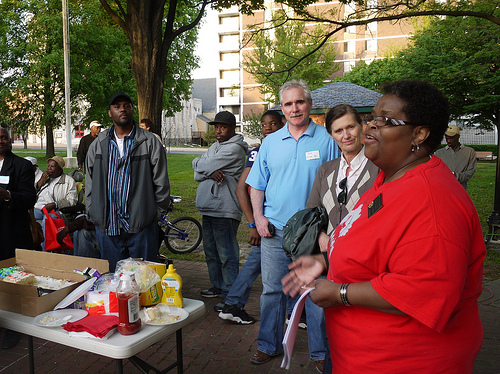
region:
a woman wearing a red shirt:
[278, 79, 488, 371]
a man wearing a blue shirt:
[248, 78, 339, 372]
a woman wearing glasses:
[282, 76, 485, 372]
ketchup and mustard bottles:
[117, 264, 183, 336]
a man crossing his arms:
[192, 108, 248, 300]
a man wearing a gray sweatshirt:
[192, 111, 249, 304]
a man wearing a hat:
[192, 108, 252, 303]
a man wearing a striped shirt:
[80, 90, 172, 266]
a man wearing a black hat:
[82, 88, 172, 260]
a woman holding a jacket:
[283, 104, 380, 372]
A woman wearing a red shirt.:
[361, 65, 451, 365]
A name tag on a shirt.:
[298, 148, 323, 162]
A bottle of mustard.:
[155, 262, 188, 307]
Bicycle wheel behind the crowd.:
[163, 214, 204, 254]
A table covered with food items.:
[1, 251, 197, 363]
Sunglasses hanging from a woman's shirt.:
[335, 175, 355, 207]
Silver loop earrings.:
[410, 141, 422, 155]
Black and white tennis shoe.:
[219, 298, 254, 328]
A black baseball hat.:
[209, 108, 239, 128]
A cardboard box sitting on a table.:
[3, 246, 110, 318]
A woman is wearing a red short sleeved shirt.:
[358, 69, 475, 354]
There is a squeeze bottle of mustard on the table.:
[158, 251, 187, 313]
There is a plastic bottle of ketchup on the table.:
[114, 261, 153, 364]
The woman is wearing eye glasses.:
[367, 93, 427, 181]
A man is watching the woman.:
[80, 78, 168, 283]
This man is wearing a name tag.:
[261, 68, 337, 215]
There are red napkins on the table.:
[73, 305, 123, 350]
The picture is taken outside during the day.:
[4, 12, 499, 172]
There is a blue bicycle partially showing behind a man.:
[164, 167, 218, 274]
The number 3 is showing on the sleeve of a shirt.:
[249, 132, 272, 185]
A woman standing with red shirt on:
[291, 65, 495, 370]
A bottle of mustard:
[150, 257, 190, 307]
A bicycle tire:
[159, 205, 205, 261]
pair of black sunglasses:
[336, 176, 350, 208]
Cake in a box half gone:
[0, 249, 89, 319]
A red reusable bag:
[38, 204, 79, 255]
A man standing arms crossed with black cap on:
[193, 106, 243, 303]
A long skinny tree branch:
[243, 5, 498, 78]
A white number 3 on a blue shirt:
[238, 142, 270, 173]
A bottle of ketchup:
[111, 268, 147, 338]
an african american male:
[93, 95, 163, 260]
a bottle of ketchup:
[110, 267, 145, 334]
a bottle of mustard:
[161, 261, 186, 309]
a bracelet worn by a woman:
[338, 276, 353, 307]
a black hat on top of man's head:
[206, 111, 238, 128]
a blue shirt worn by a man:
[248, 121, 345, 233]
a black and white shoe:
[221, 302, 256, 327]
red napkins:
[61, 308, 118, 335]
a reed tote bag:
[39, 204, 74, 252]